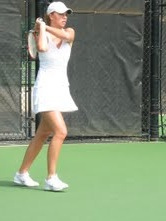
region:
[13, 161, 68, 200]
the girl is wearing white tennis shoes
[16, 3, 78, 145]
the girl is playing tennis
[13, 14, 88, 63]
the girl is swinging the raquette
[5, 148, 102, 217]
the tennis court is green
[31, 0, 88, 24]
the girl is wearing a white cap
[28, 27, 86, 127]
the girl is dressed in a white tennis dress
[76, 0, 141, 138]
the backdrop is grey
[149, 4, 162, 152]
the gate has hinges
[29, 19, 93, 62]
the girl's top is a vee neck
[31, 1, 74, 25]
the girl has her hair pulled back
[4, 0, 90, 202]
Tennis player with a racket on right side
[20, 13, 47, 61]
Tennis player holds the racket with both hands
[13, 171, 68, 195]
White shoes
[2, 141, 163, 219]
Tennis court is green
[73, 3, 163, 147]
Fence of tennis court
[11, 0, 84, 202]
Tennis player wears a white dress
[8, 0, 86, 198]
Tennis player has a white hat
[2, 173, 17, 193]
Shadow of tennis player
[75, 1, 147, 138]
Tennis court is cover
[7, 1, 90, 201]
Tennis player hold rack over right shoulder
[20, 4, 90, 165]
tennis player in white skirt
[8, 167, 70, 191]
sneakers on two feet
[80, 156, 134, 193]
plain green tennis court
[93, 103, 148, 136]
chain link fence along court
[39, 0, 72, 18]
white cap on player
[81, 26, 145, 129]
plastic cover on fence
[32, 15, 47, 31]
two hands on grip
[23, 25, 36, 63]
racquet held behind player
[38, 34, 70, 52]
elbows of tennis player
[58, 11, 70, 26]
face on tennis player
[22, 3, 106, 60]
Tennis play after hitting ball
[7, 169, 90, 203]
White sneakers on the tennis player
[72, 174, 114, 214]
Green tennis court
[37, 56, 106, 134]
Women wearing tennis skirt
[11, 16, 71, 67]
Women holding tennis racket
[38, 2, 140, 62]
Tennis player with a white hate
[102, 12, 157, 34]
Tennis fence with blind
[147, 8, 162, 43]
Chain link fence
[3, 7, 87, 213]
Tennis player on the court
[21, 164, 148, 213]
Tennis court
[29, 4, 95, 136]
A woman playing tennis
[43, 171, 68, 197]
A white sneaker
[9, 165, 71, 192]
A pair of white sneakers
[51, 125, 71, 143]
A knee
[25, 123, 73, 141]
A pair of knees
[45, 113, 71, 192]
A leg bent at the knee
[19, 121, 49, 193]
A straight leg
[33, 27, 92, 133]
A white tennis dress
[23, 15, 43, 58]
A tennis racket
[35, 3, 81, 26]
A woman wearing a white hat